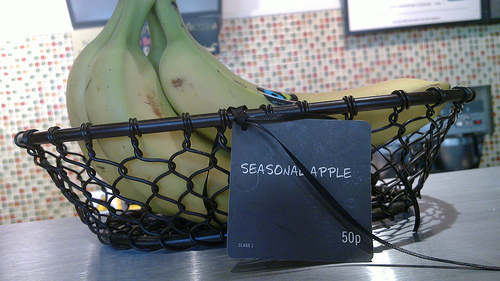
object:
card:
[226, 118, 373, 262]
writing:
[241, 163, 351, 179]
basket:
[15, 86, 475, 252]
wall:
[0, 0, 499, 226]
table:
[2, 167, 500, 281]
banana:
[147, 0, 450, 149]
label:
[257, 86, 298, 106]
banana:
[65, 0, 229, 227]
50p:
[341, 231, 361, 246]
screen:
[67, 2, 223, 30]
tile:
[253, 19, 277, 38]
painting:
[343, 0, 489, 34]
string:
[232, 105, 500, 269]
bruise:
[172, 78, 183, 87]